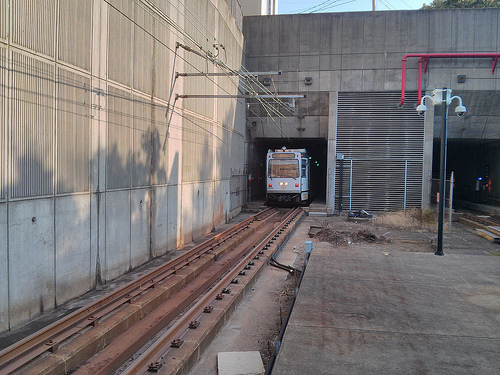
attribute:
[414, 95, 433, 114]
light — white 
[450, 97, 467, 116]
light — white 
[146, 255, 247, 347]
tracks — rust colored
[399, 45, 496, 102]
pipes — red 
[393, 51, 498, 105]
pipes — magenta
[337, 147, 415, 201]
pipes — blue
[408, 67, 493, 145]
cameras — pictured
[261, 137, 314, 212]
train — silver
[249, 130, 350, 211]
train — light blue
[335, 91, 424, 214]
door — sliding, metal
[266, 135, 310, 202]
engine — blue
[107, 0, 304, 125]
cables — power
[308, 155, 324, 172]
lights — green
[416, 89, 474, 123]
lights — white 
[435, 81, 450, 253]
pole — metal 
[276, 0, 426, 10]
sky — blue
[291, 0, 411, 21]
sky — clear, blue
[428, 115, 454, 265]
pole — grey , metal 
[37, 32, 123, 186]
wall — grey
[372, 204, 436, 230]
grass — dry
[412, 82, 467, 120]
cameras — security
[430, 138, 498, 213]
tunnel — darkened 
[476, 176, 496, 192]
lights — blue, red